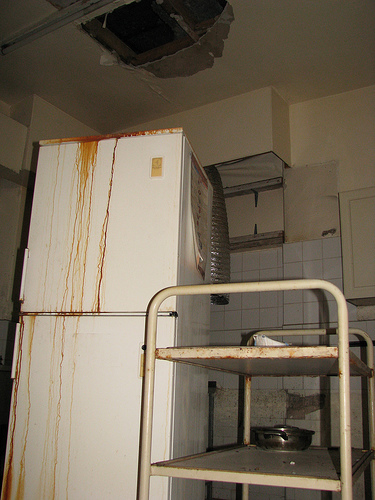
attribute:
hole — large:
[69, 1, 214, 57]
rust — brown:
[72, 138, 101, 216]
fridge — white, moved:
[3, 126, 213, 499]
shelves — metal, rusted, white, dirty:
[139, 278, 373, 492]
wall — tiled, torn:
[241, 238, 345, 278]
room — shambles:
[4, 2, 373, 499]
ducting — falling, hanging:
[200, 166, 242, 307]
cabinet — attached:
[326, 186, 374, 306]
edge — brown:
[171, 347, 181, 350]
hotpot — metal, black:
[245, 419, 317, 453]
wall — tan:
[289, 102, 374, 181]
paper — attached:
[183, 147, 213, 281]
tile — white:
[305, 238, 322, 261]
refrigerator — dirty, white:
[24, 128, 229, 499]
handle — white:
[9, 321, 28, 381]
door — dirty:
[15, 309, 172, 497]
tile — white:
[301, 261, 324, 279]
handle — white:
[18, 244, 33, 305]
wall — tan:
[189, 105, 269, 154]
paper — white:
[252, 334, 295, 348]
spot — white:
[104, 53, 117, 70]